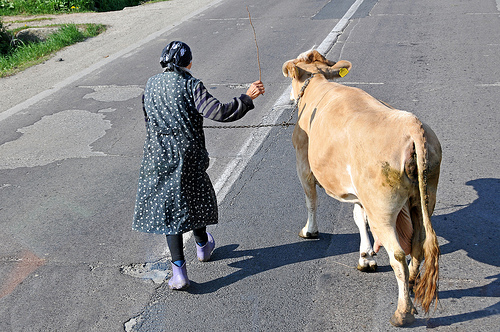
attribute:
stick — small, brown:
[245, 7, 264, 83]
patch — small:
[2, 2, 144, 77]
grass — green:
[2, 0, 144, 75]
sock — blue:
[173, 259, 183, 264]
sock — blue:
[197, 241, 206, 244]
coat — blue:
[141, 67, 249, 225]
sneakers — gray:
[141, 247, 195, 293]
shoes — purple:
[165, 235, 233, 296]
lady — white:
[100, 24, 274, 299]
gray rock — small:
[20, 29, 43, 36]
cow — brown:
[274, 39, 454, 329]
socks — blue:
[166, 235, 204, 257]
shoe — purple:
[191, 232, 215, 262]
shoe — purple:
[162, 258, 192, 289]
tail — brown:
[381, 131, 489, 323]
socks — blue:
[141, 223, 261, 288]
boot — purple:
[163, 260, 195, 294]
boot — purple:
[195, 232, 218, 262]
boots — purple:
[165, 232, 215, 290]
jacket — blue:
[139, 68, 249, 235]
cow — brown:
[281, 46, 443, 327]